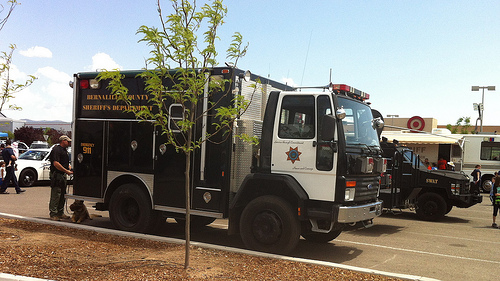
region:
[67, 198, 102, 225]
German shepherd under truck.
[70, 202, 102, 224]
Police dog awaiting orders.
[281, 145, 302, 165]
Star symbol on door of truck.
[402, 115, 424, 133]
Brand name symbol for Target.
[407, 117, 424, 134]
Red and white bull eyes.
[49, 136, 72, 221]
Police officer dressed in fatigues.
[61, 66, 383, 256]
Black and white armored police truck.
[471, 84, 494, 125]
Light pole atop the building.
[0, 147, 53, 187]
White police car parked in space.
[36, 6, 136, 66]
Powder blue sky with white fluffy clouds.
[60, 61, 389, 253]
truck parked in lot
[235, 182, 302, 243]
tire on side of vehicle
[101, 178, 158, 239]
tire on side of vehicle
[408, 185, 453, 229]
tire on side of vehicle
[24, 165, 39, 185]
tire on side of vehicle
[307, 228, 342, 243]
tire on side of vehicle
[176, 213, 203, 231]
tire on side of vehicle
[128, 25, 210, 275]
tree in flower bed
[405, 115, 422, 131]
logo on side of building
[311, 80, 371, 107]
lights on top of truck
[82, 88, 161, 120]
an orange sign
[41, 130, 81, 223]
a man working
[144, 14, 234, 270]
a green tree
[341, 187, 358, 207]
a headlight on a rescue truck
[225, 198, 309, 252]
the front wheel on a rescue truck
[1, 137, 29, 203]
a man walking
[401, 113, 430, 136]
a bulls eye symbol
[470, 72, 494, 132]
a tower in the air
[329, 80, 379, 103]
the lights on an emergency vehicle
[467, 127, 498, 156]
a camper window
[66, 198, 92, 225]
dog is resting in shade of truck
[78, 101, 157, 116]
truck is from the sheriff's department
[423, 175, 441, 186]
truck is from the swat unit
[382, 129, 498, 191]
Recreational vehicle has letters FF visible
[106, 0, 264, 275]
young tree has green leaves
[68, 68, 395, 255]
sheriff's department truck is black and white with lights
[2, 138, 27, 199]
Man is holding his child while walking in parking lot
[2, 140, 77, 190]
white police car is visible in the background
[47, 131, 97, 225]
Man is holding the dog with a leash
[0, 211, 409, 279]
island is dirt with no green grass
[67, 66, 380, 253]
major police truck outside of target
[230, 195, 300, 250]
big police truck tires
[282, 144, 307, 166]
police emblem on door of truck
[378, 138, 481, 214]
extra back up military police presence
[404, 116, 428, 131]
target store symbol on building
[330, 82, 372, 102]
lights on the top of cab on police truck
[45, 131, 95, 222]
man standing with police dog next to truck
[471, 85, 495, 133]
lights for night time in parking lot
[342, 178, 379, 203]
front grill and lights on truck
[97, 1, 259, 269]
very young tree in fron of truck